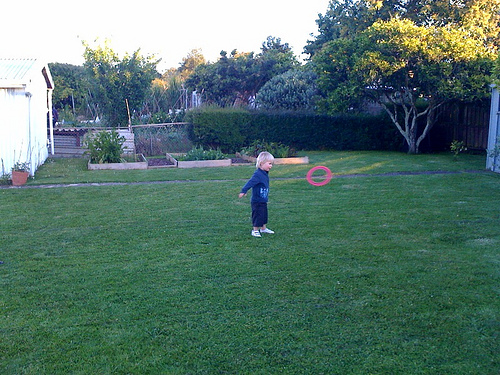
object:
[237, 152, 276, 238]
boy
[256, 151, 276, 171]
head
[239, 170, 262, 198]
arm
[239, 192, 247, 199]
hand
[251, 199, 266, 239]
leg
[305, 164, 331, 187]
disc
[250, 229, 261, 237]
shoe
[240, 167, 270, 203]
shirt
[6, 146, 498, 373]
grass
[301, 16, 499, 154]
tree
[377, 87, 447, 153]
trunk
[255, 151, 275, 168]
hair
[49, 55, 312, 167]
graden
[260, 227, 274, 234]
shoe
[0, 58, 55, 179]
shed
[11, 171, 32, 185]
pot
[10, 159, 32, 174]
plant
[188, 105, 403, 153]
bush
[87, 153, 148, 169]
planter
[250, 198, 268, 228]
shorts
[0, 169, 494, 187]
sidewalk